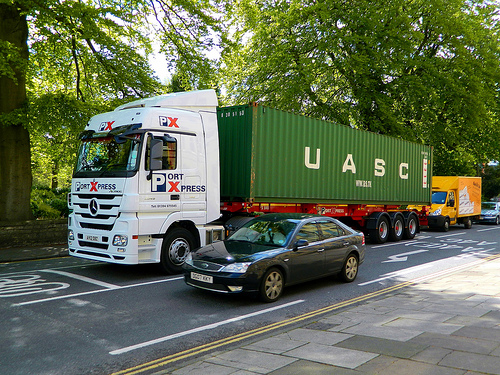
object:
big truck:
[63, 89, 431, 268]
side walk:
[122, 257, 500, 375]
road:
[0, 219, 500, 375]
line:
[109, 299, 304, 358]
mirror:
[147, 139, 163, 181]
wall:
[1, 219, 67, 248]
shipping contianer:
[215, 107, 430, 217]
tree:
[222, 0, 500, 177]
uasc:
[305, 146, 409, 179]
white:
[184, 146, 210, 171]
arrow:
[381, 250, 430, 263]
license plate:
[190, 271, 213, 283]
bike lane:
[0, 266, 117, 308]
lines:
[107, 247, 498, 375]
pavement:
[150, 257, 499, 375]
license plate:
[83, 234, 102, 240]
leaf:
[469, 33, 477, 40]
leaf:
[423, 14, 433, 17]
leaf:
[369, 12, 370, 14]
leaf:
[339, 37, 341, 47]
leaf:
[312, 9, 323, 15]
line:
[214, 341, 235, 346]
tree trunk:
[0, 1, 33, 220]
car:
[184, 210, 364, 301]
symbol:
[0, 273, 69, 298]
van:
[409, 176, 482, 232]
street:
[2, 223, 500, 375]